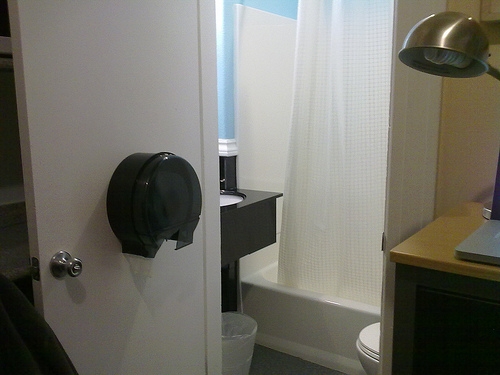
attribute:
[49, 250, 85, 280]
knob — silver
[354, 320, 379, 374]
toilet — blocked, white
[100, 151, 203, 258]
holder — black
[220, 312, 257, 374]
basket — white, clear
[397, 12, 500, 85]
lamp — metal, silver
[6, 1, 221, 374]
door — white, open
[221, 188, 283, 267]
counter — marble, black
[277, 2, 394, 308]
curtain — white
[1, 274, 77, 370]
clothing — dark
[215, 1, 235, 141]
wall — blue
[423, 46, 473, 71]
bulb — efficient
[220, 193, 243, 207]
sink — white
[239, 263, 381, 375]
bathtub — white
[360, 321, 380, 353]
lid — white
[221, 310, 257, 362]
bag — plastic